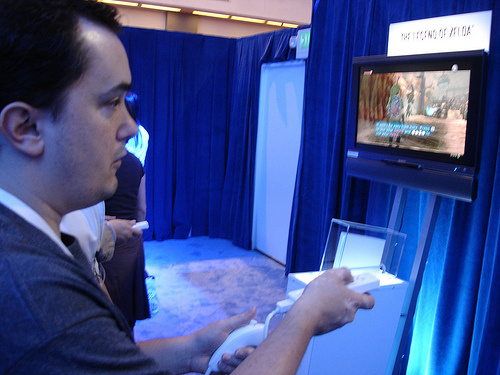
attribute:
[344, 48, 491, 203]
television — black, flat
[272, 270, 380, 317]
controller — white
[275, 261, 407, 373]
gaming system — white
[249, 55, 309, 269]
frame — rectangular, white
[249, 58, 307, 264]
door — white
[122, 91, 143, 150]
hair — long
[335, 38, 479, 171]
flat screen — displaying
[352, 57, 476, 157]
screen — displaying Video game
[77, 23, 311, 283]
drapes — blue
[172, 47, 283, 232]
curtain — blue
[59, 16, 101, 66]
hair line — receding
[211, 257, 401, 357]
controller — gaming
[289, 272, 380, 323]
game controller — Nintendo Wii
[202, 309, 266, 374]
game controller — Nintendo Wii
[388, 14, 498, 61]
sign — white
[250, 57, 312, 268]
door — white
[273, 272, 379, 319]
wii controller — white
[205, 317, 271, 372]
wii controller — white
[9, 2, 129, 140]
hair — thinning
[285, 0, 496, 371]
curtain — blue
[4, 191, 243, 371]
shirt — black